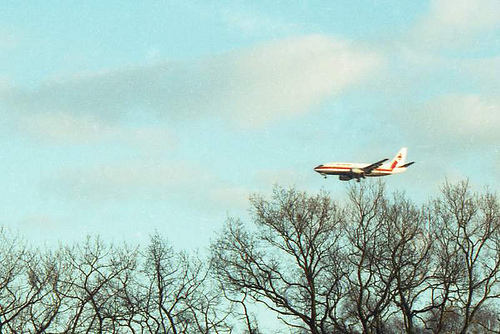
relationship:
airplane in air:
[313, 146, 416, 183] [1, 2, 498, 331]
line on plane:
[307, 156, 376, 185] [301, 144, 419, 185]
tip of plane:
[308, 153, 327, 180] [310, 143, 422, 200]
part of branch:
[303, 265, 318, 300] [301, 260, 313, 301]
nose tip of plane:
[311, 164, 326, 174] [313, 144, 418, 181]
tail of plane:
[389, 147, 408, 170] [312, 145, 413, 180]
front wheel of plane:
[324, 172, 330, 180] [315, 146, 417, 183]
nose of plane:
[313, 160, 324, 176] [312, 145, 413, 180]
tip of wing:
[381, 154, 387, 163] [363, 155, 389, 172]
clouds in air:
[207, 46, 376, 121] [1, 0, 498, 332]